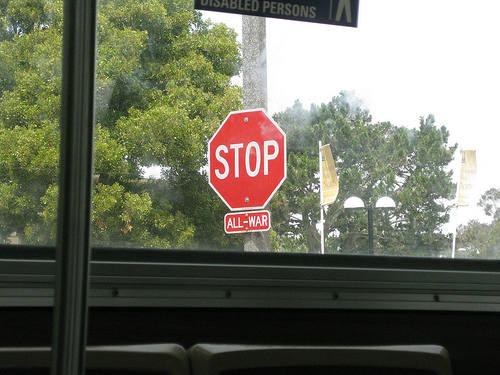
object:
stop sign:
[205, 106, 287, 210]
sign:
[222, 209, 272, 234]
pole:
[238, 13, 273, 254]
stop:
[214, 140, 279, 178]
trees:
[0, 0, 500, 258]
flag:
[318, 143, 340, 208]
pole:
[317, 137, 325, 254]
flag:
[456, 146, 478, 209]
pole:
[449, 144, 460, 257]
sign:
[192, 0, 361, 29]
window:
[91, 2, 499, 261]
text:
[200, 1, 315, 21]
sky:
[137, 0, 500, 236]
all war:
[225, 213, 267, 229]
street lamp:
[341, 193, 367, 210]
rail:
[51, 1, 98, 374]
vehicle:
[0, 0, 500, 373]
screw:
[109, 289, 120, 298]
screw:
[431, 293, 443, 303]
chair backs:
[188, 338, 457, 374]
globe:
[373, 193, 396, 212]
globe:
[339, 195, 365, 210]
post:
[366, 207, 377, 255]